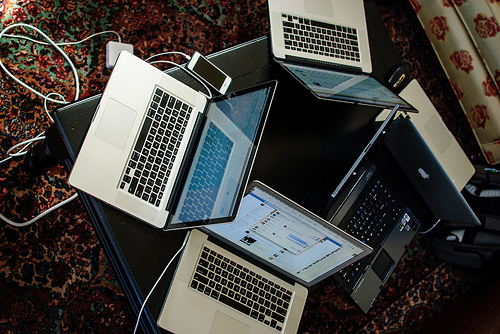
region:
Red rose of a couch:
[447, 45, 473, 76]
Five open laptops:
[65, 0, 482, 332]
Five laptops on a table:
[66, 0, 481, 332]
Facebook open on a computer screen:
[202, 190, 341, 282]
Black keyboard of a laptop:
[113, 84, 195, 208]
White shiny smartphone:
[185, 47, 232, 97]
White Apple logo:
[415, 163, 432, 183]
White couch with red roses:
[408, 0, 498, 170]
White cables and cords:
[2, 20, 211, 242]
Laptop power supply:
[101, 38, 133, 71]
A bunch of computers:
[10, 4, 487, 319]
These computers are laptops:
[14, 2, 491, 324]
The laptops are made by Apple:
[402, 148, 437, 188]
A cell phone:
[173, 42, 243, 97]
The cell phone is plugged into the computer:
[134, 37, 236, 101]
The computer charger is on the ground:
[15, 18, 141, 88]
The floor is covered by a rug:
[10, 23, 68, 295]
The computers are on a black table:
[52, 23, 469, 320]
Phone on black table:
[187, 50, 234, 94]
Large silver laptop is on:
[68, 48, 278, 233]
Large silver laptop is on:
[156, 177, 373, 332]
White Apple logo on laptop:
[417, 167, 429, 182]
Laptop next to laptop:
[67, 49, 278, 230]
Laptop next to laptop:
[155, 178, 378, 332]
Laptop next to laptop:
[326, 103, 420, 312]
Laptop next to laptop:
[375, 78, 485, 228]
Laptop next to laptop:
[269, 0, 421, 114]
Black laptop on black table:
[324, 102, 425, 312]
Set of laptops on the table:
[63, 2, 486, 332]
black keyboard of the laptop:
[116, 84, 194, 209]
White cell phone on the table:
[182, 49, 232, 93]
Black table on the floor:
[22, 5, 485, 332]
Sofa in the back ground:
[406, 0, 498, 170]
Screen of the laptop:
[164, 80, 279, 232]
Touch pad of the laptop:
[92, 96, 139, 152]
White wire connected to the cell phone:
[143, 48, 193, 60]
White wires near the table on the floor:
[0, 21, 145, 231]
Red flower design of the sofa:
[448, 47, 476, 75]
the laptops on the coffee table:
[74, 0, 474, 322]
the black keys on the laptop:
[117, 82, 189, 211]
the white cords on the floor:
[0, 8, 71, 243]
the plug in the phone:
[177, 49, 196, 65]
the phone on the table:
[182, 49, 238, 94]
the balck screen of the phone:
[191, 56, 226, 88]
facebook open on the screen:
[219, 202, 340, 282]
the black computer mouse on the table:
[380, 55, 415, 94]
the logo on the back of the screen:
[417, 160, 430, 182]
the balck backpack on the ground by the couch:
[440, 149, 498, 300]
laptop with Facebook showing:
[147, 180, 394, 326]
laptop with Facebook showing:
[152, 179, 387, 327]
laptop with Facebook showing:
[149, 175, 376, 330]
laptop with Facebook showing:
[149, 175, 382, 331]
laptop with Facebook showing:
[151, 172, 390, 329]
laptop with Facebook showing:
[150, 175, 370, 332]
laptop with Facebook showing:
[150, 165, 373, 332]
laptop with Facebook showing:
[142, 178, 377, 333]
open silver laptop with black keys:
[66, 50, 278, 230]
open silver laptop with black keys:
[153, 181, 373, 323]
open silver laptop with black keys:
[265, 0, 412, 112]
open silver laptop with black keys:
[326, 102, 422, 321]